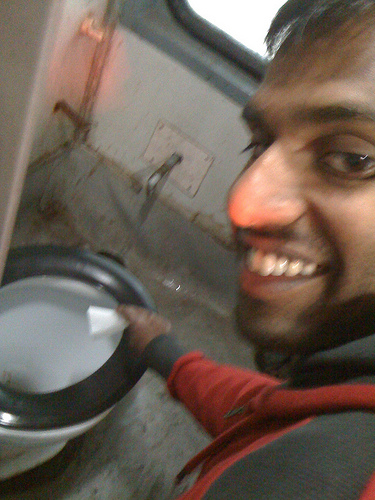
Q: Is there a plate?
A: Yes, there is a plate.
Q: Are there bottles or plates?
A: Yes, there is a plate.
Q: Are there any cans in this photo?
A: No, there are no cans.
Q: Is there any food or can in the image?
A: No, there are no cans or food.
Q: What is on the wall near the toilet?
A: The plate is on the wall.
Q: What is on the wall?
A: The plate is on the wall.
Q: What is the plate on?
A: The plate is on the wall.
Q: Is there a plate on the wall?
A: Yes, there is a plate on the wall.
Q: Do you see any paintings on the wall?
A: No, there is a plate on the wall.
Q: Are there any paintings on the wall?
A: No, there is a plate on the wall.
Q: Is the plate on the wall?
A: Yes, the plate is on the wall.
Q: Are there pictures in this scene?
A: No, there are no pictures.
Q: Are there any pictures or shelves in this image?
A: No, there are no pictures or shelves.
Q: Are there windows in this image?
A: Yes, there is a window.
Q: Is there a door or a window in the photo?
A: Yes, there is a window.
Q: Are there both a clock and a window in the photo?
A: No, there is a window but no clocks.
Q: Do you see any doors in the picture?
A: No, there are no doors.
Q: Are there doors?
A: No, there are no doors.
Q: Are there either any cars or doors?
A: No, there are no doors or cars.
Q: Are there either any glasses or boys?
A: No, there are no glasses or boys.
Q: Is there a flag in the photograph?
A: No, there are no flags.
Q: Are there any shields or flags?
A: No, there are no flags or shields.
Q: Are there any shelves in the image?
A: No, there are no shelves.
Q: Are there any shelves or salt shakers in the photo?
A: No, there are no shelves or salt shakers.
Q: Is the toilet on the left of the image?
A: Yes, the toilet is on the left of the image.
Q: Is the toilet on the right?
A: No, the toilet is on the left of the image.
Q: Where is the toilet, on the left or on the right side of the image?
A: The toilet is on the left of the image.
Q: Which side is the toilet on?
A: The toilet is on the left of the image.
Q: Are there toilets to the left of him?
A: Yes, there is a toilet to the left of the man.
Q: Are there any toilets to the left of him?
A: Yes, there is a toilet to the left of the man.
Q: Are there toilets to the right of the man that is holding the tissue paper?
A: No, the toilet is to the left of the man.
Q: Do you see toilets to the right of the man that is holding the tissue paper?
A: No, the toilet is to the left of the man.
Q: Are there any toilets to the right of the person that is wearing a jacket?
A: No, the toilet is to the left of the man.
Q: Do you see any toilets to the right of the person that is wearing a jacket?
A: No, the toilet is to the left of the man.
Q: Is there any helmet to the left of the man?
A: No, there is a toilet to the left of the man.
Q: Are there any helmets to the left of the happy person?
A: No, there is a toilet to the left of the man.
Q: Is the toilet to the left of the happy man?
A: Yes, the toilet is to the left of the man.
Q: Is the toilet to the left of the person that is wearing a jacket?
A: Yes, the toilet is to the left of the man.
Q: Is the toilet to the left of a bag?
A: No, the toilet is to the left of the man.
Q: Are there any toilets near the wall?
A: Yes, there is a toilet near the wall.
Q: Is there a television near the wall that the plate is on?
A: No, there is a toilet near the wall.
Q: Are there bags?
A: No, there are no bags.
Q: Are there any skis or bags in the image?
A: No, there are no bags or skis.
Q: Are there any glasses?
A: No, there are no glasses.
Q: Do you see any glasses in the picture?
A: No, there are no glasses.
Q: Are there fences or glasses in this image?
A: No, there are no glasses or fences.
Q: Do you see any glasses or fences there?
A: No, there are no glasses or fences.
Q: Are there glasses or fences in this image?
A: No, there are no glasses or fences.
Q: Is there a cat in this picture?
A: No, there are no cats.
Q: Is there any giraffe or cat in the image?
A: No, there are no cats or giraffes.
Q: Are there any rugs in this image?
A: No, there are no rugs.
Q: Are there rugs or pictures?
A: No, there are no rugs or pictures.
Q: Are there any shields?
A: No, there are no shields.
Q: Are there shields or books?
A: No, there are no shields or books.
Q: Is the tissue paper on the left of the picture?
A: Yes, the tissue paper is on the left of the image.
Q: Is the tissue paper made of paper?
A: No, the tissue paper is made of cloth.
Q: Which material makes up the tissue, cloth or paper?
A: The tissue is made of cloth.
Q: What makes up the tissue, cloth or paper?
A: The tissue is made of cloth.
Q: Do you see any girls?
A: No, there are no girls.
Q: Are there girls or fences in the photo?
A: No, there are no girls or fences.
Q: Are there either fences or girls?
A: No, there are no girls or fences.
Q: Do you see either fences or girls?
A: No, there are no girls or fences.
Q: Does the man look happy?
A: Yes, the man is happy.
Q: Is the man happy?
A: Yes, the man is happy.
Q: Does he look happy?
A: Yes, the man is happy.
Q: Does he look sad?
A: No, the man is happy.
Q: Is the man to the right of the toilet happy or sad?
A: The man is happy.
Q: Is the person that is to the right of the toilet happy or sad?
A: The man is happy.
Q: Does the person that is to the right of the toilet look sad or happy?
A: The man is happy.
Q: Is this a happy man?
A: Yes, this is a happy man.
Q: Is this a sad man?
A: No, this is a happy man.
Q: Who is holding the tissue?
A: The man is holding the tissue.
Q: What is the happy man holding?
A: The man is holding the tissue paper.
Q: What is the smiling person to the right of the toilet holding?
A: The man is holding the tissue paper.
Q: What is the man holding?
A: The man is holding the tissue paper.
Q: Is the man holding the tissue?
A: Yes, the man is holding the tissue.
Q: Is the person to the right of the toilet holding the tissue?
A: Yes, the man is holding the tissue.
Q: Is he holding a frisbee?
A: No, the man is holding the tissue.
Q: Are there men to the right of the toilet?
A: Yes, there is a man to the right of the toilet.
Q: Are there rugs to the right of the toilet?
A: No, there is a man to the right of the toilet.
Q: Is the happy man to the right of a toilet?
A: Yes, the man is to the right of a toilet.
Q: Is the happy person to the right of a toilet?
A: Yes, the man is to the right of a toilet.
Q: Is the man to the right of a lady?
A: No, the man is to the right of a toilet.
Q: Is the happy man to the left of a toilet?
A: No, the man is to the right of a toilet.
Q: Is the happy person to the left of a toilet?
A: No, the man is to the right of a toilet.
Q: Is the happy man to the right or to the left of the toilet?
A: The man is to the right of the toilet.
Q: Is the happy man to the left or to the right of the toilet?
A: The man is to the right of the toilet.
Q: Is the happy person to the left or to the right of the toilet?
A: The man is to the right of the toilet.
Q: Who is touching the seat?
A: The man is touching the seat.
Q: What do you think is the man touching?
A: The man is touching the seat.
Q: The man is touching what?
A: The man is touching the seat.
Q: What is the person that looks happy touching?
A: The man is touching the seat.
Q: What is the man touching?
A: The man is touching the seat.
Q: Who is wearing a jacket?
A: The man is wearing a jacket.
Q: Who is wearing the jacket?
A: The man is wearing a jacket.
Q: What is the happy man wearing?
A: The man is wearing a jacket.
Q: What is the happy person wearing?
A: The man is wearing a jacket.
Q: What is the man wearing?
A: The man is wearing a jacket.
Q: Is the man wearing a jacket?
A: Yes, the man is wearing a jacket.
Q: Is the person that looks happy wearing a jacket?
A: Yes, the man is wearing a jacket.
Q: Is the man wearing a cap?
A: No, the man is wearing a jacket.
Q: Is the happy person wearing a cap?
A: No, the man is wearing a jacket.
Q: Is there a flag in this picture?
A: No, there are no flags.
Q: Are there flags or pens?
A: No, there are no flags or pens.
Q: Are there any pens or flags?
A: No, there are no flags or pens.